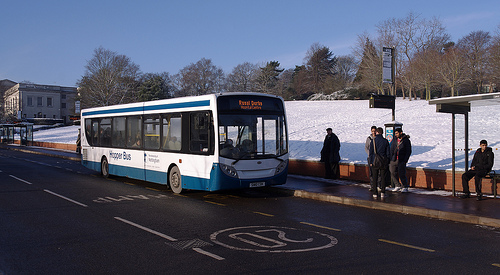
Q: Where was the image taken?
A: It was taken at the road.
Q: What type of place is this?
A: It is a road.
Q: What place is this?
A: It is a road.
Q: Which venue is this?
A: This is a road.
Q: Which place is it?
A: It is a road.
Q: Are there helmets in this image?
A: No, there are no helmets.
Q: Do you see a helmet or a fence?
A: No, there are no helmets or fences.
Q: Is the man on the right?
A: Yes, the man is on the right of the image.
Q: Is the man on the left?
A: No, the man is on the right of the image.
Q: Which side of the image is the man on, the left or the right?
A: The man is on the right of the image.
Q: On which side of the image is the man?
A: The man is on the right of the image.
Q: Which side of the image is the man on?
A: The man is on the right of the image.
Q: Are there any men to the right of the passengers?
A: Yes, there is a man to the right of the passengers.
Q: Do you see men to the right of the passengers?
A: Yes, there is a man to the right of the passengers.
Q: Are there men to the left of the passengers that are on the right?
A: No, the man is to the right of the passengers.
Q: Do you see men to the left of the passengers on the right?
A: No, the man is to the right of the passengers.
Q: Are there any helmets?
A: No, there are no helmets.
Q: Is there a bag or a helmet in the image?
A: No, there are no helmets or bags.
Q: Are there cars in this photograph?
A: No, there are no cars.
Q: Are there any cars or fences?
A: No, there are no cars or fences.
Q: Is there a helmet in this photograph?
A: No, there are no helmets.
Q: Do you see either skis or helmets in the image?
A: No, there are no helmets or skis.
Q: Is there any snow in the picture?
A: Yes, there is snow.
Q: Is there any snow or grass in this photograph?
A: Yes, there is snow.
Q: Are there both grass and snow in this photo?
A: No, there is snow but no grass.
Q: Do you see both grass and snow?
A: No, there is snow but no grass.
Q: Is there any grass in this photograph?
A: No, there is no grass.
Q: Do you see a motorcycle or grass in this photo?
A: No, there are no grass or motorcycles.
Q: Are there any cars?
A: No, there are no cars.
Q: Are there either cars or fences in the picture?
A: No, there are no cars or fences.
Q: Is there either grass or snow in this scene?
A: Yes, there is snow.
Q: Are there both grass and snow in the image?
A: No, there is snow but no grass.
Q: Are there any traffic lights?
A: No, there are no traffic lights.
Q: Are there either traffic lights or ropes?
A: No, there are no traffic lights or ropes.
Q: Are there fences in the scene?
A: No, there are no fences.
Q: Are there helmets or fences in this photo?
A: No, there are no fences or helmets.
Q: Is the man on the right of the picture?
A: Yes, the man is on the right of the image.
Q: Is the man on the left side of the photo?
A: No, the man is on the right of the image.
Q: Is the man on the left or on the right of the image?
A: The man is on the right of the image.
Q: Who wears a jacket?
A: The man wears a jacket.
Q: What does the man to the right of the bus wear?
A: The man wears a jacket.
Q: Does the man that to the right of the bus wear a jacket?
A: Yes, the man wears a jacket.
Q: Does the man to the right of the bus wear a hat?
A: No, the man wears a jacket.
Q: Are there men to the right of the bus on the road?
A: Yes, there is a man to the right of the bus.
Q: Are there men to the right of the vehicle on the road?
A: Yes, there is a man to the right of the bus.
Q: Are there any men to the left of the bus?
A: No, the man is to the right of the bus.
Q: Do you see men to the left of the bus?
A: No, the man is to the right of the bus.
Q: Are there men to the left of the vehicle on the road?
A: No, the man is to the right of the bus.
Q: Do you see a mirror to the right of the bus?
A: No, there is a man to the right of the bus.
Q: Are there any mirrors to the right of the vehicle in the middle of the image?
A: No, there is a man to the right of the bus.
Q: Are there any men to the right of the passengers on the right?
A: Yes, there is a man to the right of the passengers.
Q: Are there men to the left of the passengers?
A: No, the man is to the right of the passengers.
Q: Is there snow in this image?
A: Yes, there is snow.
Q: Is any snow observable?
A: Yes, there is snow.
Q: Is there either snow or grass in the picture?
A: Yes, there is snow.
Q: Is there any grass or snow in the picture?
A: Yes, there is snow.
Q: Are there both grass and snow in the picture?
A: No, there is snow but no grass.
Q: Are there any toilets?
A: No, there are no toilets.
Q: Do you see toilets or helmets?
A: No, there are no toilets or helmets.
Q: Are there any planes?
A: No, there are no planes.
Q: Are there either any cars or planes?
A: No, there are no planes or cars.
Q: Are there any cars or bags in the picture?
A: No, there are no cars or bags.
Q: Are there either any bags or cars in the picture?
A: No, there are no cars or bags.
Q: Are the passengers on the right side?
A: Yes, the passengers are on the right of the image.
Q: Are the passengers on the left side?
A: No, the passengers are on the right of the image.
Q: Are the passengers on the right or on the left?
A: The passengers are on the right of the image.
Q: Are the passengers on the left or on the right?
A: The passengers are on the right of the image.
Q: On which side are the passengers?
A: The passengers are on the right of the image.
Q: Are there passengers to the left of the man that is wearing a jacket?
A: Yes, there are passengers to the left of the man.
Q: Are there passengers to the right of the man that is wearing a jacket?
A: No, the passengers are to the left of the man.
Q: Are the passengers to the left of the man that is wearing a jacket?
A: Yes, the passengers are to the left of the man.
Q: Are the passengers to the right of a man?
A: No, the passengers are to the left of a man.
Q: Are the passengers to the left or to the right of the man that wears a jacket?
A: The passengers are to the left of the man.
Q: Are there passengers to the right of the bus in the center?
A: Yes, there are passengers to the right of the bus.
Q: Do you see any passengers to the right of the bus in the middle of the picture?
A: Yes, there are passengers to the right of the bus.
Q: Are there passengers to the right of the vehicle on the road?
A: Yes, there are passengers to the right of the bus.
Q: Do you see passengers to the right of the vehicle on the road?
A: Yes, there are passengers to the right of the bus.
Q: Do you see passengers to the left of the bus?
A: No, the passengers are to the right of the bus.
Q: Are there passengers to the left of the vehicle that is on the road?
A: No, the passengers are to the right of the bus.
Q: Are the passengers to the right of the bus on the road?
A: Yes, the passengers are to the right of the bus.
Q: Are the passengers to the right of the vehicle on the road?
A: Yes, the passengers are to the right of the bus.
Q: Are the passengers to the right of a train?
A: No, the passengers are to the right of the bus.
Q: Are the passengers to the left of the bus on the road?
A: No, the passengers are to the right of the bus.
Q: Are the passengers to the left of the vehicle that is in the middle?
A: No, the passengers are to the right of the bus.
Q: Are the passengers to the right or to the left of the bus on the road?
A: The passengers are to the right of the bus.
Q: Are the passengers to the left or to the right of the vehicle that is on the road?
A: The passengers are to the right of the bus.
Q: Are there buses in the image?
A: Yes, there is a bus.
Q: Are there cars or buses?
A: Yes, there is a bus.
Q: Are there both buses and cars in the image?
A: No, there is a bus but no cars.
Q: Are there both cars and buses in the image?
A: No, there is a bus but no cars.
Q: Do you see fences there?
A: No, there are no fences.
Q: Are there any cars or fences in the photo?
A: No, there are no fences or cars.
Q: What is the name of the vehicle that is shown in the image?
A: The vehicle is a bus.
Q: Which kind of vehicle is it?
A: The vehicle is a bus.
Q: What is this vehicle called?
A: This is a bus.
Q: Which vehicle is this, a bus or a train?
A: This is a bus.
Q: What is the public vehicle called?
A: The vehicle is a bus.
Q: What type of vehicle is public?
A: The vehicle is a bus.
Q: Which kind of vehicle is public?
A: The vehicle is a bus.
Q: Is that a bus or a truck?
A: That is a bus.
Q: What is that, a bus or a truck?
A: That is a bus.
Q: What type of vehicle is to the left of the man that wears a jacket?
A: The vehicle is a bus.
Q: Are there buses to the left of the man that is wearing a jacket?
A: Yes, there is a bus to the left of the man.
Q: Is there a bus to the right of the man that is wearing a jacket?
A: No, the bus is to the left of the man.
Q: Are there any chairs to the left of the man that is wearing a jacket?
A: No, there is a bus to the left of the man.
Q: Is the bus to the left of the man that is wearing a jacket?
A: Yes, the bus is to the left of the man.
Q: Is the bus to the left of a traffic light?
A: No, the bus is to the left of the man.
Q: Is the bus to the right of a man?
A: No, the bus is to the left of a man.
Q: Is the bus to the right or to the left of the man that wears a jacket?
A: The bus is to the left of the man.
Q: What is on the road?
A: The bus is on the road.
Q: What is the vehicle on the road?
A: The vehicle is a bus.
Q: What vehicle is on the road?
A: The vehicle is a bus.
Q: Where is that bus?
A: The bus is on the road.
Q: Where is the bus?
A: The bus is on the road.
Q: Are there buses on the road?
A: Yes, there is a bus on the road.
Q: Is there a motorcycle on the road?
A: No, there is a bus on the road.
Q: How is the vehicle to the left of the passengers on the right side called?
A: The vehicle is a bus.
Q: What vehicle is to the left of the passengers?
A: The vehicle is a bus.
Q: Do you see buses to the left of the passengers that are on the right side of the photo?
A: Yes, there is a bus to the left of the passengers.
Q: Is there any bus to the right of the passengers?
A: No, the bus is to the left of the passengers.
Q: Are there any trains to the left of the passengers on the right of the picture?
A: No, there is a bus to the left of the passengers.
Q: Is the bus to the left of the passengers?
A: Yes, the bus is to the left of the passengers.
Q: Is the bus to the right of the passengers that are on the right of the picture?
A: No, the bus is to the left of the passengers.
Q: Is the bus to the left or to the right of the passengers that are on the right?
A: The bus is to the left of the passengers.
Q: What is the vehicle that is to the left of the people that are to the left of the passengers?
A: The vehicle is a bus.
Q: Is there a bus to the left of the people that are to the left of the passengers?
A: Yes, there is a bus to the left of the people.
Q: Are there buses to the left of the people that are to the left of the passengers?
A: Yes, there is a bus to the left of the people.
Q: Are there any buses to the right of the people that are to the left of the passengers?
A: No, the bus is to the left of the people.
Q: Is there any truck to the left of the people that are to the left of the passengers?
A: No, there is a bus to the left of the people.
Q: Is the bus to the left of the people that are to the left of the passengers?
A: Yes, the bus is to the left of the people.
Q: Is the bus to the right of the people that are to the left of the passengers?
A: No, the bus is to the left of the people.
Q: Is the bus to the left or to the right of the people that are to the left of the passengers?
A: The bus is to the left of the people.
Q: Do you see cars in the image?
A: No, there are no cars.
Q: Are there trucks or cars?
A: No, there are no cars or trucks.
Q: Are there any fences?
A: No, there are no fences.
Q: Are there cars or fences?
A: No, there are no fences or cars.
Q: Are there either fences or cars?
A: No, there are no fences or cars.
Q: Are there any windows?
A: Yes, there are windows.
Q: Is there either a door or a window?
A: Yes, there are windows.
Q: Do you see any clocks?
A: No, there are no clocks.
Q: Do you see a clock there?
A: No, there are no clocks.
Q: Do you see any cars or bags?
A: No, there are no cars or bags.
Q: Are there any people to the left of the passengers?
A: Yes, there are people to the left of the passengers.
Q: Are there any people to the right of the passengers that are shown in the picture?
A: No, the people are to the left of the passengers.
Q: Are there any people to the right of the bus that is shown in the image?
A: Yes, there are people to the right of the bus.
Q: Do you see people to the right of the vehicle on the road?
A: Yes, there are people to the right of the bus.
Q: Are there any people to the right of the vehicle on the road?
A: Yes, there are people to the right of the bus.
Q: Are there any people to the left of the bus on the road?
A: No, the people are to the right of the bus.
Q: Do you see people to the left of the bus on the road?
A: No, the people are to the right of the bus.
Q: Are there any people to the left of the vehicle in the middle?
A: No, the people are to the right of the bus.